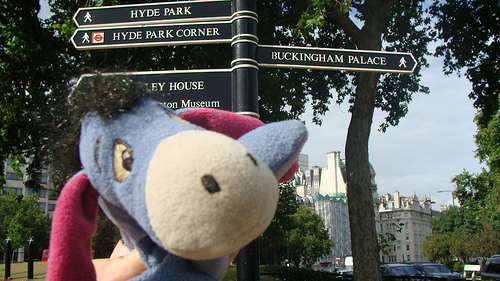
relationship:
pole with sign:
[232, 8, 262, 279] [257, 41, 416, 72]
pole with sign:
[232, 8, 262, 279] [74, 68, 231, 110]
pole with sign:
[232, 8, 262, 279] [67, 20, 232, 51]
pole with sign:
[232, 8, 262, 279] [68, 0, 234, 27]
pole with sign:
[213, 7, 285, 127] [144, 78, 239, 111]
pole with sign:
[213, 7, 285, 127] [272, 49, 428, 77]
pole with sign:
[230, 0, 259, 117] [70, 0, 257, 27]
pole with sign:
[230, 0, 259, 117] [70, 16, 258, 49]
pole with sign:
[230, 0, 259, 117] [230, 38, 416, 73]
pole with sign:
[230, 0, 259, 117] [63, 62, 258, 116]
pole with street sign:
[232, 8, 262, 279] [256, 36, 418, 73]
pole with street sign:
[232, 8, 262, 279] [66, 65, 233, 113]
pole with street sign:
[232, 8, 262, 279] [70, 26, 247, 48]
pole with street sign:
[232, 8, 262, 279] [67, 5, 236, 33]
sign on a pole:
[65, 67, 229, 114] [231, 0, 260, 279]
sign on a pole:
[257, 41, 416, 72] [231, 0, 260, 279]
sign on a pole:
[69, 23, 235, 51] [231, 0, 260, 279]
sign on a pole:
[71, 3, 231, 21] [231, 0, 260, 279]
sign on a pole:
[65, 67, 229, 114] [226, 0, 266, 118]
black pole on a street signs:
[231, 2, 258, 279] [69, 2, 416, 122]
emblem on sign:
[396, 53, 412, 74] [71, 3, 223, 24]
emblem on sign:
[262, 37, 424, 78] [65, 16, 230, 53]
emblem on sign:
[262, 37, 424, 78] [65, 65, 218, 115]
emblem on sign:
[76, 29, 106, 45] [62, 3, 242, 18]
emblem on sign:
[76, 26, 105, 50] [253, 45, 418, 76]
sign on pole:
[71, 3, 231, 21] [210, 28, 286, 269]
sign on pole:
[69, 23, 235, 51] [210, 28, 286, 269]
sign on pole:
[257, 41, 416, 72] [210, 28, 286, 269]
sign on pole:
[65, 67, 229, 114] [210, 28, 286, 269]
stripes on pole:
[228, 7, 258, 118] [231, 0, 260, 279]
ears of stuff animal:
[177, 108, 296, 180] [42, 71, 307, 276]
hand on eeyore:
[87, 225, 248, 279] [37, 70, 309, 279]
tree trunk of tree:
[340, 94, 382, 278] [304, 6, 498, 279]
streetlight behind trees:
[448, 189, 460, 209] [7, 2, 427, 278]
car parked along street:
[379, 260, 464, 280] [314, 250, 497, 279]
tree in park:
[5, 190, 49, 261] [1, 6, 361, 278]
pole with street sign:
[232, 8, 262, 279] [261, 43, 418, 73]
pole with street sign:
[232, 8, 262, 279] [72, 0, 233, 27]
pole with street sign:
[232, 8, 262, 279] [68, 20, 230, 46]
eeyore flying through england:
[37, 70, 309, 279] [21, 8, 498, 268]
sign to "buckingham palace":
[257, 41, 416, 72] [265, 49, 389, 69]